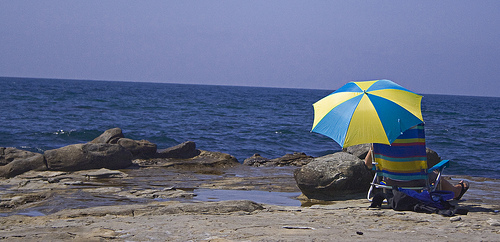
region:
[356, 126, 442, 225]
a man holding umbrella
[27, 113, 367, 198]
a group of stones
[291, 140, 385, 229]
a large stone in front of man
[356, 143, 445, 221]
a man sitting down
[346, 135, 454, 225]
a man sitting on stone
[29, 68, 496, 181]
a clear view of sea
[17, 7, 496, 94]
a beautiful view of sky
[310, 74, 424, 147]
umbrella is blue and yellow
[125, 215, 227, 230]
sand on the ground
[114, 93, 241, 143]
water in the ocean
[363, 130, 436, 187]
chair under the umbrella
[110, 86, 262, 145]
the water is calm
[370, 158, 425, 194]
back of the chair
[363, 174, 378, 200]
metal on the chair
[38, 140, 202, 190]
rock formation near water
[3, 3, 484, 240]
a scene outside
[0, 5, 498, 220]
a scene during the day time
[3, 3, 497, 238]
a scene near the ocean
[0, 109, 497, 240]
a gray stone area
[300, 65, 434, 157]
a yellow and blue umbrella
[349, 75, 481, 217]
a beach lawn chair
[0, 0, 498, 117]
a blue sky with no clouds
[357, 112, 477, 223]
a person in the chair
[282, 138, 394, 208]
a large gray rock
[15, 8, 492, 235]
a person looking at the water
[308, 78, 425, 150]
a yellow and blue umbrella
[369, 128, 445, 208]
a blue and yellow chair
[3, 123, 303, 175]
rocks on the shore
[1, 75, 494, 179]
a blue sky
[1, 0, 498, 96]
a blue clear sky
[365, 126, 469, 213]
a person sitting in a chair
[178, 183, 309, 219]
water on the shore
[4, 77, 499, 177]
waves in the water washing ashore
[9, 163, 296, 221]
pools of water in the rocky area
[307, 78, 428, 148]
a blue and yellow umbrella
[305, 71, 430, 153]
a yellow and blue umbrella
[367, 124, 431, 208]
a yellow and blue chair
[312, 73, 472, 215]
a person sitting in a chair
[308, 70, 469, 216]
a person sitting in a yellow and blue chair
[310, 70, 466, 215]
a person under a yellow and blue umbrella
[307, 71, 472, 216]
a person resting under an umbrella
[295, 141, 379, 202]
a boulder by a chair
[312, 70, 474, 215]
a person looking at the ocean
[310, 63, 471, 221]
someone resting by the sea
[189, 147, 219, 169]
A rock on the ground.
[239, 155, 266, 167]
A rock on the ground.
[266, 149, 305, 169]
A rock on the ground.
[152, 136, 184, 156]
A rock on the ground.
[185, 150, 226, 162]
A rock on the ground.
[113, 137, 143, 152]
A rock on the ground.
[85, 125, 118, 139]
A rock on the ground.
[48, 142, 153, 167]
A rock on the ground.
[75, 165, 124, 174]
A rock on the ground.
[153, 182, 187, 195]
A rock on the ground.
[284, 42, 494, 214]
umbrella in the background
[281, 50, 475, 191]
blue and yellow umbrella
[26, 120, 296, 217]
rocks on the ground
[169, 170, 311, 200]
water on the ground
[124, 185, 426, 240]
sand on the ground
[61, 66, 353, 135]
ocean in the background